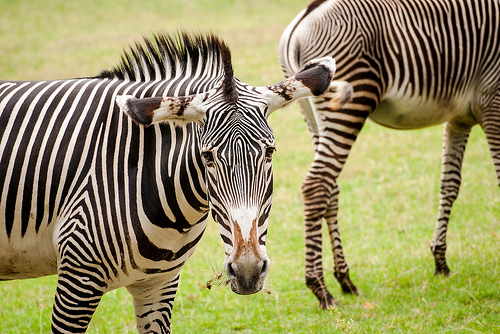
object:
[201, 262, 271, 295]
food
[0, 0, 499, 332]
grass field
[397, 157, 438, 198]
ground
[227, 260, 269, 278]
nose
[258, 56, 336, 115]
ear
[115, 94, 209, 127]
ear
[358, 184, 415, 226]
grass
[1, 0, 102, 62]
grass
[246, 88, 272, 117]
ground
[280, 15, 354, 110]
tail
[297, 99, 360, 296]
legs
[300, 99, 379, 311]
legs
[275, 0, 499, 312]
zebra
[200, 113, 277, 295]
face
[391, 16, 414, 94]
stripe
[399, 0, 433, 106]
stripe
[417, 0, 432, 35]
stripe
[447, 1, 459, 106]
stripe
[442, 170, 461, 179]
stripe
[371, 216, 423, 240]
weeds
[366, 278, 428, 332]
grass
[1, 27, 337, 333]
zebra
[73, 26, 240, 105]
hair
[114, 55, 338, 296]
view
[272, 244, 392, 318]
camera